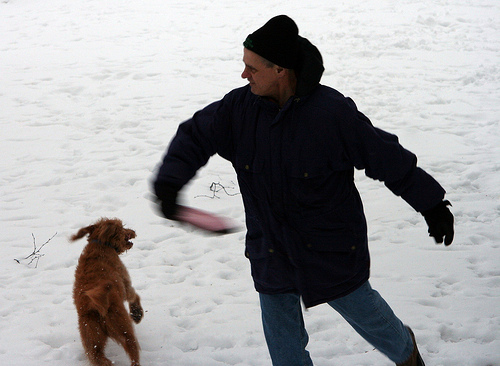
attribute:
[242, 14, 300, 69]
hat — black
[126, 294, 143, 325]
dog's paw — underside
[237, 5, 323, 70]
hat — black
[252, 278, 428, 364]
jeans — blue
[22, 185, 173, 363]
dog — running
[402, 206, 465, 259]
glove — black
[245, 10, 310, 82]
hat — black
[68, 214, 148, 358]
dog — medium, brown, running, fuzzy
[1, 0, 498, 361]
snow — white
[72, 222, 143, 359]
dog — running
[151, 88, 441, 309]
coat — black, dark grey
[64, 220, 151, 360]
dog — brown